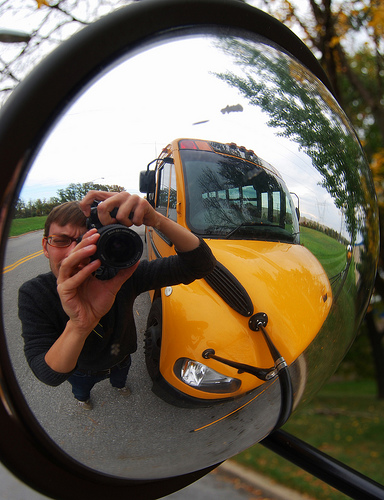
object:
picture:
[0, 0, 379, 499]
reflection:
[2, 30, 378, 476]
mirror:
[2, 30, 380, 481]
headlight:
[171, 353, 243, 395]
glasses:
[42, 233, 75, 250]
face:
[46, 219, 96, 280]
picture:
[2, 31, 381, 479]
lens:
[96, 227, 146, 271]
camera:
[76, 198, 147, 280]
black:
[142, 263, 154, 277]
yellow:
[158, 235, 335, 396]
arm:
[127, 210, 216, 300]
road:
[6, 233, 46, 275]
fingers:
[58, 258, 99, 290]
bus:
[138, 137, 333, 407]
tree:
[238, 0, 384, 396]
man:
[19, 190, 217, 410]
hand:
[55, 225, 141, 328]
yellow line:
[0, 251, 44, 281]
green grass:
[228, 323, 384, 500]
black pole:
[258, 427, 384, 498]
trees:
[65, 182, 115, 205]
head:
[41, 199, 116, 290]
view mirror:
[139, 168, 156, 192]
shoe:
[76, 393, 94, 414]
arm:
[18, 289, 98, 387]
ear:
[42, 237, 49, 257]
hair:
[43, 201, 93, 226]